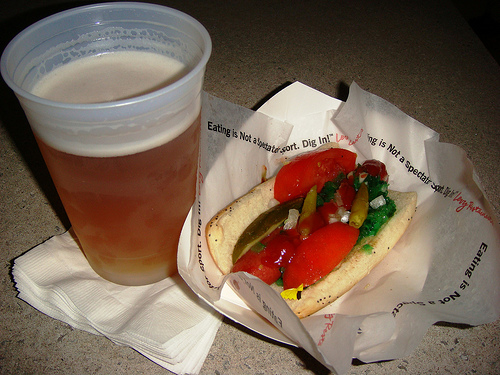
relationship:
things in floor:
[6, 5, 448, 349] [4, 4, 499, 371]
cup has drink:
[0, 10, 216, 280] [0, 10, 216, 280]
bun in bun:
[206, 158, 424, 321] [206, 158, 424, 321]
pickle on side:
[225, 193, 306, 263] [207, 134, 299, 330]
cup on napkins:
[0, 10, 216, 280] [10, 207, 225, 364]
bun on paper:
[206, 158, 424, 321] [185, 71, 487, 369]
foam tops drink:
[18, 43, 209, 141] [0, 10, 216, 280]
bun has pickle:
[206, 158, 424, 321] [225, 193, 306, 263]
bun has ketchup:
[206, 158, 424, 321] [251, 221, 303, 270]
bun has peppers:
[206, 158, 424, 321] [297, 169, 374, 235]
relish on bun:
[310, 162, 393, 235] [206, 158, 424, 321]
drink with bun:
[0, 10, 216, 280] [206, 158, 424, 321]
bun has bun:
[206, 158, 424, 321] [206, 158, 424, 321]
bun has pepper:
[206, 158, 424, 321] [297, 169, 374, 235]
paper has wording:
[185, 71, 487, 369] [201, 107, 337, 150]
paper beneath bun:
[185, 71, 487, 369] [206, 158, 424, 321]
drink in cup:
[0, 10, 216, 280] [0, 10, 216, 280]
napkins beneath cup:
[10, 207, 225, 364] [0, 10, 216, 280]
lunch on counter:
[6, 5, 448, 349] [4, 4, 499, 371]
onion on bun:
[284, 195, 388, 228] [206, 158, 424, 321]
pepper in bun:
[270, 222, 374, 286] [206, 158, 424, 321]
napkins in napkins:
[29, 150, 226, 327] [10, 207, 225, 364]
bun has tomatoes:
[206, 158, 424, 321] [269, 147, 358, 201]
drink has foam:
[0, 10, 216, 280] [18, 43, 209, 141]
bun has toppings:
[206, 158, 424, 321] [235, 159, 396, 281]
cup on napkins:
[0, 10, 216, 280] [29, 150, 226, 327]